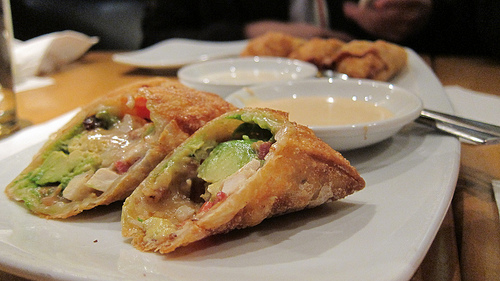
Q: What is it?
A: Food.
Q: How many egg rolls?
A: 2.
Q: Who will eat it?
A: People.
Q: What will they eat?
A: Food.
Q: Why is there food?
A: They are hungry.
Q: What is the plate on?
A: Table.